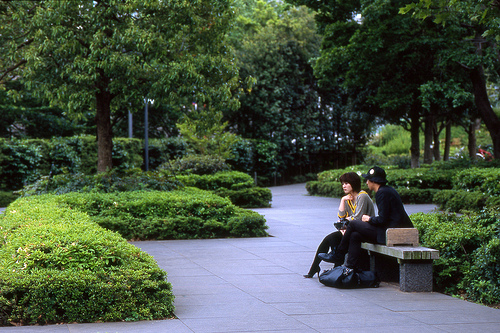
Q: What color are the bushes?
A: Green.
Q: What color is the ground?
A: Brown.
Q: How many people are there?
A: Two.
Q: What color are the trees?
A: Green.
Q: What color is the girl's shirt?
A: Gray.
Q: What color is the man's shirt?
A: Black.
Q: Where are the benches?
A: On the path.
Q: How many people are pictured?
A: Two.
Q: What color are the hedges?
A: Green.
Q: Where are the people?
A: In a park.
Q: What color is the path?
A: Grey.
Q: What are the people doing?
A: Sitting on a bench.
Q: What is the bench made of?
A: Stone.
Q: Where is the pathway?
A: Through the park.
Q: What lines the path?
A: Bushes.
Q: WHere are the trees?
A: Lining the paths.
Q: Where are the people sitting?
A: On the bench.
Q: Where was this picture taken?
A: A park.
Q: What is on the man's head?
A: A hat.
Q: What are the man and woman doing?
A: Talking.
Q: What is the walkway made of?
A: Cement.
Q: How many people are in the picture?
A: Two.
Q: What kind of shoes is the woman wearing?
A: High heels.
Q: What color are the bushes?
A: Green.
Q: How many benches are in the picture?
A: One.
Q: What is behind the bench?
A: Bushes.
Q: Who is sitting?
A: Two women.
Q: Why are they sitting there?
A: To visit one another.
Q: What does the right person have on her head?
A: A hat.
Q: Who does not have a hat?
A: The girl on the left.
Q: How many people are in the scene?
A: 2.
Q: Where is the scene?
A: A public park.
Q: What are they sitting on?
A: A concrete bench.